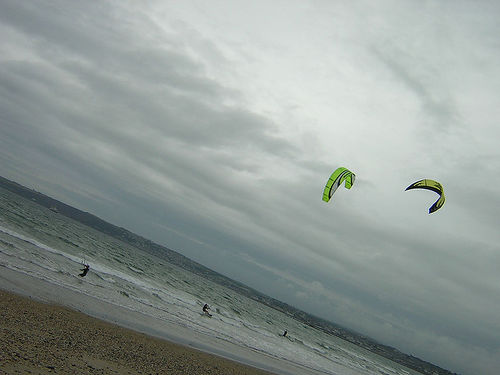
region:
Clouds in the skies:
[158, 96, 278, 178]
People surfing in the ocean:
[63, 251, 248, 336]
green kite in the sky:
[322, 158, 358, 205]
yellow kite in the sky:
[400, 163, 455, 218]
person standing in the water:
[70, 258, 97, 285]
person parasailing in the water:
[194, 295, 219, 317]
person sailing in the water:
[74, 252, 96, 280]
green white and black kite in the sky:
[318, 158, 360, 205]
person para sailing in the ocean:
[198, 300, 217, 319]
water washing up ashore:
[111, 268, 176, 325]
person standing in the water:
[75, 253, 98, 279]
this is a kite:
[313, 158, 359, 201]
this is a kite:
[404, 170, 450, 216]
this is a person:
[77, 255, 94, 280]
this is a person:
[202, 295, 217, 317]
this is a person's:
[280, 328, 296, 340]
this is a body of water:
[3, 195, 68, 288]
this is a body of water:
[92, 217, 189, 319]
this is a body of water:
[212, 271, 273, 356]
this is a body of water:
[295, 323, 414, 373]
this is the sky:
[25, 5, 498, 197]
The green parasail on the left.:
[321, 166, 357, 202]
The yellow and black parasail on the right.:
[404, 176, 449, 219]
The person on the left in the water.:
[76, 260, 88, 279]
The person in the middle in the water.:
[199, 301, 210, 317]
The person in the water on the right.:
[282, 326, 286, 336]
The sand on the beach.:
[4, 294, 276, 374]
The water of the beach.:
[8, 195, 473, 374]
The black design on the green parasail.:
[326, 166, 359, 197]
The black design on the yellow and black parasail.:
[411, 176, 444, 212]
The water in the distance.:
[16, 178, 483, 374]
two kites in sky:
[310, 164, 465, 248]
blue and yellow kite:
[370, 146, 470, 233]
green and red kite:
[290, 156, 360, 258]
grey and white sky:
[133, 59, 221, 188]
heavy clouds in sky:
[200, 106, 334, 276]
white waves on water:
[88, 236, 186, 326]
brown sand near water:
[43, 339, 168, 373]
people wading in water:
[27, 255, 302, 295]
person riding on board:
[169, 300, 227, 320]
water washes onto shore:
[56, 274, 190, 343]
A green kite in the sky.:
[321, 163, 354, 207]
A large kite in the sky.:
[404, 177, 448, 217]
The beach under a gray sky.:
[1, 176, 453, 373]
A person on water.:
[78, 263, 90, 280]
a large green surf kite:
[404, 178, 444, 215]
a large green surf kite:
[321, 165, 353, 199]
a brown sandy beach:
[0, 287, 270, 374]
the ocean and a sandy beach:
[0, 180, 448, 374]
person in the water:
[77, 263, 89, 277]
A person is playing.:
[78, 260, 95, 277]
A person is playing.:
[201, 304, 213, 320]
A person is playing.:
[281, 330, 288, 340]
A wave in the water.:
[153, 290, 166, 301]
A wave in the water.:
[113, 290, 129, 300]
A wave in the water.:
[123, 260, 145, 276]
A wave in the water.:
[52, 265, 84, 284]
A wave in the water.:
[181, 278, 190, 288]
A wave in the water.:
[228, 305, 246, 317]